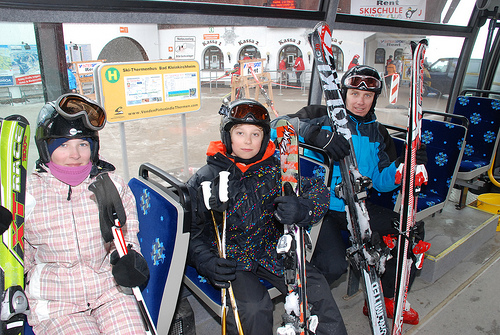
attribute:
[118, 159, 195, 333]
seat — blue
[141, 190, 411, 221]
bus seat — blue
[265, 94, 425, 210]
jacket — blue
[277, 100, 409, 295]
ski gear — blue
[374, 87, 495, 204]
chair — empty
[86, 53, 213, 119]
sign — yellow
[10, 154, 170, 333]
suit — pink, plaid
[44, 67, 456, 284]
people — these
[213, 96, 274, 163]
helmet — black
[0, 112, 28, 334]
skis — green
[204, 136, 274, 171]
hood — orange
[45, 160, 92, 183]
scarf — purple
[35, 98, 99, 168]
helmet — black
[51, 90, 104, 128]
goggles — orange